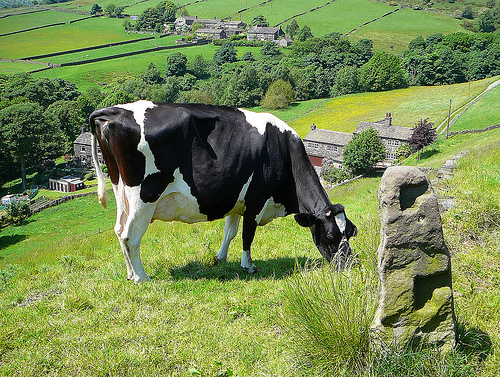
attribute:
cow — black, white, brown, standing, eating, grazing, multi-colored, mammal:
[80, 92, 361, 285]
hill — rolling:
[7, 145, 499, 371]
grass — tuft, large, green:
[284, 249, 381, 360]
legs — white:
[114, 202, 265, 278]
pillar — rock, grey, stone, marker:
[372, 167, 469, 364]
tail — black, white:
[82, 112, 118, 208]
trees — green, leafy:
[1, 27, 497, 175]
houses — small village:
[127, 5, 295, 51]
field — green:
[0, 6, 238, 89]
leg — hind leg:
[123, 179, 158, 288]